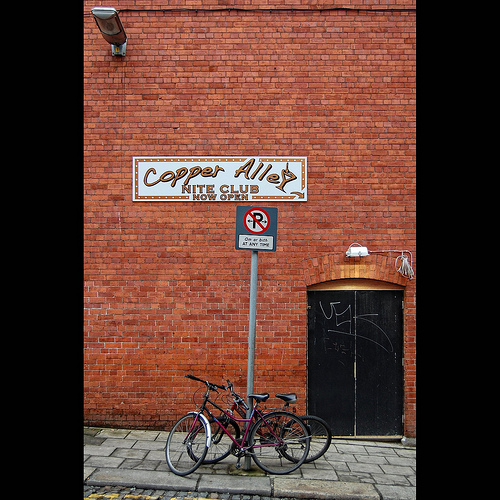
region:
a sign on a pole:
[225, 189, 310, 322]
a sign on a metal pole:
[222, 193, 279, 332]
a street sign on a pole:
[204, 204, 303, 357]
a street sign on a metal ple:
[211, 194, 314, 408]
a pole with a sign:
[239, 216, 279, 379]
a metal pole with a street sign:
[214, 182, 325, 460]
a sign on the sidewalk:
[215, 191, 335, 494]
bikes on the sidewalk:
[169, 337, 445, 499]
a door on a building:
[278, 228, 462, 495]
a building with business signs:
[117, 118, 492, 315]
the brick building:
[83, 0, 414, 437]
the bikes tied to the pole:
[165, 372, 331, 476]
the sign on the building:
[131, 155, 307, 200]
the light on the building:
[90, 6, 127, 57]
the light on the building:
[345, 244, 368, 256]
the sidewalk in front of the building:
[83, 426, 415, 499]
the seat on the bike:
[247, 392, 269, 402]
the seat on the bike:
[273, 391, 296, 403]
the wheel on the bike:
[165, 412, 207, 474]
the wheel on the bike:
[249, 410, 310, 475]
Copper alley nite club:
[120, 146, 322, 210]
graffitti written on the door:
[299, 233, 418, 457]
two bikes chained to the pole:
[155, 362, 340, 488]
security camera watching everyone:
[84, 4, 172, 71]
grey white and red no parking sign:
[215, 201, 295, 299]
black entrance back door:
[296, 278, 413, 448]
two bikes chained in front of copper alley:
[122, 150, 416, 483]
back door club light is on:
[289, 241, 416, 463]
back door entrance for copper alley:
[283, 233, 419, 440]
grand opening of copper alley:
[115, 138, 409, 477]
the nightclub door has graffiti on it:
[308, 290, 402, 436]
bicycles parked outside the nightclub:
[163, 370, 337, 477]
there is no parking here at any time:
[232, 202, 279, 253]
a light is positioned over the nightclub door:
[342, 239, 374, 260]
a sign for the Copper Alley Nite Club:
[128, 147, 315, 207]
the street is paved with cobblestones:
[84, 480, 303, 498]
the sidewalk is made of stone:
[84, 423, 412, 498]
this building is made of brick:
[86, 61, 413, 431]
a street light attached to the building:
[89, 4, 136, 60]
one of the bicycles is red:
[182, 395, 287, 451]